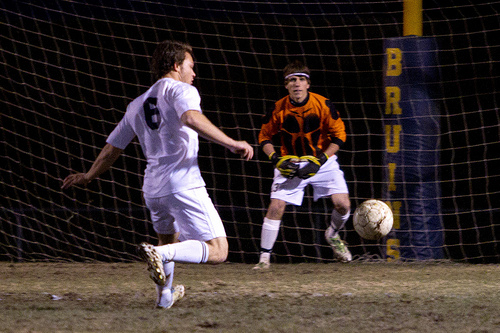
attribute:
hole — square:
[352, 164, 371, 184]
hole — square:
[416, 163, 439, 183]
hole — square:
[455, 207, 479, 231]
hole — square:
[48, 201, 73, 221]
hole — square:
[352, 136, 367, 153]